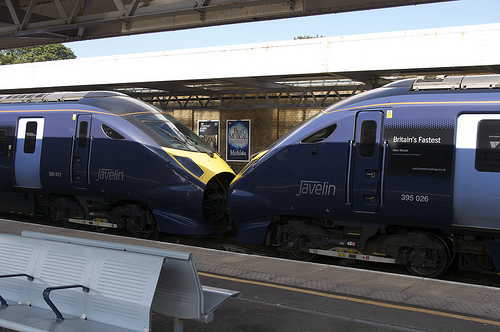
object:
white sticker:
[294, 178, 339, 197]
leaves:
[9, 43, 76, 59]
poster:
[224, 119, 251, 162]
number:
[400, 193, 430, 203]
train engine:
[225, 72, 498, 277]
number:
[45, 169, 62, 178]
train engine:
[0, 92, 234, 243]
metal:
[5, 224, 166, 323]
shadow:
[3, 130, 219, 225]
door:
[347, 107, 387, 214]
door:
[12, 116, 46, 189]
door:
[68, 112, 95, 187]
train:
[230, 74, 498, 286]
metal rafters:
[0, 0, 447, 49]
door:
[451, 110, 498, 232]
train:
[1, 73, 498, 283]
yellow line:
[278, 283, 363, 305]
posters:
[195, 111, 253, 163]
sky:
[135, 6, 447, 38]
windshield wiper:
[155, 128, 207, 155]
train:
[0, 67, 217, 234]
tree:
[0, 38, 78, 66]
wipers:
[146, 119, 214, 157]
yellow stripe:
[347, 100, 499, 109]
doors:
[449, 108, 499, 231]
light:
[4, 91, 207, 152]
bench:
[0, 230, 243, 332]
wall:
[253, 101, 291, 130]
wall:
[196, 104, 267, 118]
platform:
[1, 219, 476, 329]